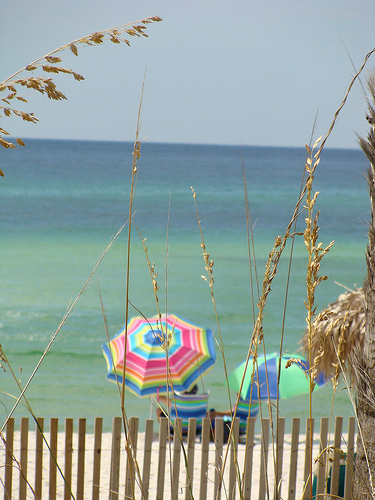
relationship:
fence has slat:
[0, 414, 359, 498] [2, 415, 17, 498]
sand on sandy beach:
[100, 449, 109, 494] [7, 416, 344, 495]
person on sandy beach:
[217, 388, 239, 423] [7, 416, 344, 495]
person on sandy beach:
[155, 381, 197, 404] [7, 416, 344, 495]